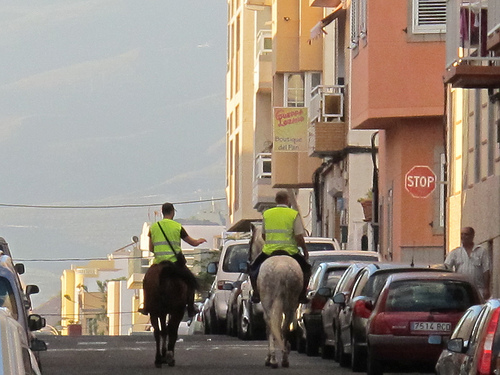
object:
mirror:
[446, 338, 463, 353]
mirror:
[353, 298, 373, 318]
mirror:
[332, 293, 346, 304]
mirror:
[217, 282, 233, 290]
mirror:
[207, 262, 218, 275]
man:
[432, 226, 493, 303]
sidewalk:
[432, 283, 487, 361]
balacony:
[307, 84, 345, 123]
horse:
[255, 254, 304, 369]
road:
[41, 328, 345, 374]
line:
[0, 197, 229, 208]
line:
[13, 251, 201, 262]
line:
[34, 311, 141, 316]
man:
[138, 202, 208, 318]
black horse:
[142, 261, 190, 369]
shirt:
[443, 246, 490, 301]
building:
[348, 0, 444, 265]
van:
[208, 237, 343, 332]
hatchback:
[351, 271, 488, 375]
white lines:
[41, 341, 272, 352]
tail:
[159, 261, 200, 290]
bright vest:
[149, 219, 182, 265]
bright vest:
[261, 207, 300, 257]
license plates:
[410, 321, 451, 331]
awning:
[307, 7, 345, 46]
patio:
[438, 2, 500, 89]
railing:
[443, 4, 476, 64]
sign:
[404, 165, 436, 198]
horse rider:
[248, 190, 312, 304]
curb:
[409, 354, 437, 367]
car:
[349, 270, 487, 373]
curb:
[395, 356, 417, 372]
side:
[1, 253, 44, 373]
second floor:
[299, 65, 492, 166]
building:
[441, 0, 500, 259]